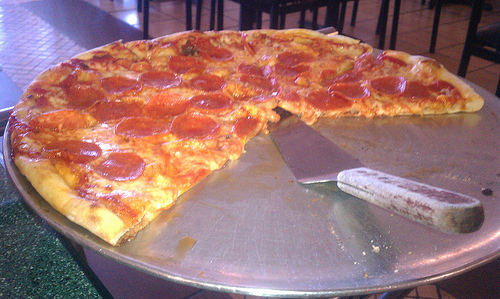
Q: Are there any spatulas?
A: Yes, there is a spatula.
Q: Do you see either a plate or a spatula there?
A: Yes, there is a spatula.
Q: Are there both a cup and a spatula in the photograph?
A: No, there is a spatula but no cups.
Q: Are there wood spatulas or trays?
A: Yes, there is a wood spatula.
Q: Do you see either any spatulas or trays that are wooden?
A: Yes, the spatula is wooden.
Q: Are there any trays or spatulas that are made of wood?
A: Yes, the spatula is made of wood.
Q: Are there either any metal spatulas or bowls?
A: Yes, there is a metal spatula.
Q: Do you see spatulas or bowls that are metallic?
A: Yes, the spatula is metallic.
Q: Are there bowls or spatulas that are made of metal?
A: Yes, the spatula is made of metal.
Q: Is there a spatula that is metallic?
A: Yes, there is a metal spatula.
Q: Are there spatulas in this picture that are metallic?
A: Yes, there is a spatula that is metallic.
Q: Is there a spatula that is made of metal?
A: Yes, there is a spatula that is made of metal.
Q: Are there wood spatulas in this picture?
A: Yes, there is a wood spatula.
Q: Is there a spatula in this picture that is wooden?
A: Yes, there is a spatula that is wooden.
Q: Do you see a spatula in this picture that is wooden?
A: Yes, there is a spatula that is wooden.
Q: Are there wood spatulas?
A: Yes, there is a spatula that is made of wood.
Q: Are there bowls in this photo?
A: No, there are no bowls.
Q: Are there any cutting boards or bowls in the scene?
A: No, there are no bowls or cutting boards.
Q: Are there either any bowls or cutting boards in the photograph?
A: No, there are no bowls or cutting boards.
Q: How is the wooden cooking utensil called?
A: The cooking utensil is a spatula.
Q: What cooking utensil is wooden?
A: The cooking utensil is a spatula.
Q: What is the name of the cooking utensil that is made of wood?
A: The cooking utensil is a spatula.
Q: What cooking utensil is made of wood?
A: The cooking utensil is a spatula.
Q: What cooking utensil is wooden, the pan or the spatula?
A: The spatula is wooden.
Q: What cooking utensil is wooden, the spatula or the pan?
A: The spatula is wooden.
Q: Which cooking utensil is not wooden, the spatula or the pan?
A: The pan is not wooden.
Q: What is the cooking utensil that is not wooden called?
A: The cooking utensil is a pan.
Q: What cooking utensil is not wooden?
A: The cooking utensil is a pan.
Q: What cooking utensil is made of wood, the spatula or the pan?
A: The spatula is made of wood.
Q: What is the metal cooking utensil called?
A: The cooking utensil is a spatula.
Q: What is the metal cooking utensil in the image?
A: The cooking utensil is a spatula.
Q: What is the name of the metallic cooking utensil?
A: The cooking utensil is a spatula.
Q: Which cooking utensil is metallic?
A: The cooking utensil is a spatula.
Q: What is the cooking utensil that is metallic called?
A: The cooking utensil is a spatula.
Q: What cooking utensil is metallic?
A: The cooking utensil is a spatula.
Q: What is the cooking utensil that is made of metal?
A: The cooking utensil is a spatula.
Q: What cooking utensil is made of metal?
A: The cooking utensil is a spatula.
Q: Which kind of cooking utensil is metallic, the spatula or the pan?
A: The spatula is metallic.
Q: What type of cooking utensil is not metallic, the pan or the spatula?
A: The pan is not metallic.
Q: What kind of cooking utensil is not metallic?
A: The cooking utensil is a pan.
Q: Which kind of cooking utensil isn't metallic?
A: The cooking utensil is a pan.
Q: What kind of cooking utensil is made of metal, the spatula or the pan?
A: The spatula is made of metal.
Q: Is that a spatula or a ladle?
A: That is a spatula.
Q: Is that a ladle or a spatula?
A: That is a spatula.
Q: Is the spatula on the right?
A: Yes, the spatula is on the right of the image.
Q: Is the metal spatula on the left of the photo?
A: No, the spatula is on the right of the image.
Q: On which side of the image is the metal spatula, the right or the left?
A: The spatula is on the right of the image.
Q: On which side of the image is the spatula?
A: The spatula is on the right of the image.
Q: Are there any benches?
A: No, there are no benches.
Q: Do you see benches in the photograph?
A: No, there are no benches.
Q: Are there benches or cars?
A: No, there are no benches or cars.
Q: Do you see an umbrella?
A: No, there are no umbrellas.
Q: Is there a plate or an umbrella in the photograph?
A: No, there are no umbrellas or plates.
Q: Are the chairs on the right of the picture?
A: Yes, the chairs are on the right of the image.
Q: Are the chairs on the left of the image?
A: No, the chairs are on the right of the image.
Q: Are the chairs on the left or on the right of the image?
A: The chairs are on the right of the image.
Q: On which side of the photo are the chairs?
A: The chairs are on the right of the image.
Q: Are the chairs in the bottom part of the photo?
A: No, the chairs are in the top of the image.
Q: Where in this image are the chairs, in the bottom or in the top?
A: The chairs are in the top of the image.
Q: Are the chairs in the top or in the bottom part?
A: The chairs are in the top of the image.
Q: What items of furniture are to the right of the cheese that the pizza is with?
A: The pieces of furniture are chairs.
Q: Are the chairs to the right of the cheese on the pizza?
A: Yes, the chairs are to the right of the cheese.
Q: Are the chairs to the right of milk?
A: No, the chairs are to the right of the cheese.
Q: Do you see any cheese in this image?
A: Yes, there is cheese.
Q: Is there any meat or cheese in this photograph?
A: Yes, there is cheese.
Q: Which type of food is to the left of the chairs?
A: The food is cheese.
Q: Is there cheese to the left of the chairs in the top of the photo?
A: Yes, there is cheese to the left of the chairs.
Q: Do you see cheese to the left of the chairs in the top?
A: Yes, there is cheese to the left of the chairs.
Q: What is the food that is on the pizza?
A: The food is cheese.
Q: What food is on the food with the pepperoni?
A: The food is cheese.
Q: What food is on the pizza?
A: The food is cheese.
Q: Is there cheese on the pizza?
A: Yes, there is cheese on the pizza.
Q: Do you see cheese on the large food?
A: Yes, there is cheese on the pizza.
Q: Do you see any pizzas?
A: Yes, there is a pizza.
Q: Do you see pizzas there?
A: Yes, there is a pizza.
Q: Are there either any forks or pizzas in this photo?
A: Yes, there is a pizza.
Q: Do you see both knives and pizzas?
A: No, there is a pizza but no knives.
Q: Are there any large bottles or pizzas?
A: Yes, there is a large pizza.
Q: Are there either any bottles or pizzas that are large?
A: Yes, the pizza is large.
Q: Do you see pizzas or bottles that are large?
A: Yes, the pizza is large.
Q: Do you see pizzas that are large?
A: Yes, there is a large pizza.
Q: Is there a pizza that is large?
A: Yes, there is a pizza that is large.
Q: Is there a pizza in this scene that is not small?
A: Yes, there is a large pizza.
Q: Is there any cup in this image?
A: No, there are no cups.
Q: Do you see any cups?
A: No, there are no cups.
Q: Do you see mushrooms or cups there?
A: No, there are no cups or mushrooms.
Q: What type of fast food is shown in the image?
A: The fast food is a pizza.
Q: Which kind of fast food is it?
A: The food is a pizza.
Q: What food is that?
A: This is a pizza.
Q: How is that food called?
A: This is a pizza.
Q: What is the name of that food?
A: This is a pizza.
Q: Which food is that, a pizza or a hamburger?
A: This is a pizza.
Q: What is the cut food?
A: The food is a pizza.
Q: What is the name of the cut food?
A: The food is a pizza.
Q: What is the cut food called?
A: The food is a pizza.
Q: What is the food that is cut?
A: The food is a pizza.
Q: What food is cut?
A: The food is a pizza.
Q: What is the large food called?
A: The food is a pizza.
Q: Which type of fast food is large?
A: The fast food is a pizza.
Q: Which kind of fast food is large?
A: The fast food is a pizza.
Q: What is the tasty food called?
A: The food is a pizza.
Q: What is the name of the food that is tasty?
A: The food is a pizza.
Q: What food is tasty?
A: The food is a pizza.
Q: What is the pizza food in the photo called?
A: The food is a pizza.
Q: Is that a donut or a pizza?
A: That is a pizza.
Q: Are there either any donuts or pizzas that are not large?
A: No, there is a pizza but it is large.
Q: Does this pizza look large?
A: Yes, the pizza is large.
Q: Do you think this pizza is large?
A: Yes, the pizza is large.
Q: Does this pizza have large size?
A: Yes, the pizza is large.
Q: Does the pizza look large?
A: Yes, the pizza is large.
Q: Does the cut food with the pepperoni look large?
A: Yes, the pizza is large.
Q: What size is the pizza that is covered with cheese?
A: The pizza is large.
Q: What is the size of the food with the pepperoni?
A: The pizza is large.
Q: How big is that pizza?
A: The pizza is large.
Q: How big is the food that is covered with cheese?
A: The pizza is large.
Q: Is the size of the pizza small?
A: No, the pizza is large.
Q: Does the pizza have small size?
A: No, the pizza is large.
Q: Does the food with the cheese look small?
A: No, the pizza is large.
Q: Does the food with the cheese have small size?
A: No, the pizza is large.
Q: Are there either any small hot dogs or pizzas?
A: No, there is a pizza but it is large.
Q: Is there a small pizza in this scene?
A: No, there is a pizza but it is large.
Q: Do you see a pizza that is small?
A: No, there is a pizza but it is large.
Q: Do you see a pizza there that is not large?
A: No, there is a pizza but it is large.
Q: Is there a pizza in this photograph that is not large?
A: No, there is a pizza but it is large.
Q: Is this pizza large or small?
A: The pizza is large.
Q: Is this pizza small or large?
A: The pizza is large.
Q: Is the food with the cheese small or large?
A: The pizza is large.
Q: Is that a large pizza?
A: Yes, that is a large pizza.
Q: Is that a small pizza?
A: No, that is a large pizza.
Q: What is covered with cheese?
A: The pizza is covered with cheese.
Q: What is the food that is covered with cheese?
A: The food is a pizza.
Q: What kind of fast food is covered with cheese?
A: The food is a pizza.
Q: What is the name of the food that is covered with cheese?
A: The food is a pizza.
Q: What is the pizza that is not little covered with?
A: The pizza is covered with cheese.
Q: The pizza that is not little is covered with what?
A: The pizza is covered with cheese.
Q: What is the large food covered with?
A: The pizza is covered with cheese.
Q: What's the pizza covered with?
A: The pizza is covered with cheese.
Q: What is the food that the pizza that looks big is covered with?
A: The food is cheese.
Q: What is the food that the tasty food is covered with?
A: The food is cheese.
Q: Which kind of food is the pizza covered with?
A: The pizza is covered with cheese.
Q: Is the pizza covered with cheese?
A: Yes, the pizza is covered with cheese.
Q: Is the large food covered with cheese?
A: Yes, the pizza is covered with cheese.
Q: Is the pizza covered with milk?
A: No, the pizza is covered with cheese.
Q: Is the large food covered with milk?
A: No, the pizza is covered with cheese.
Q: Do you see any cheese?
A: Yes, there is cheese.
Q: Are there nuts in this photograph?
A: No, there are no nuts.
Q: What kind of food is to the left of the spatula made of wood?
A: The food is cheese.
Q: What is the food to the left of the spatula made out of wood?
A: The food is cheese.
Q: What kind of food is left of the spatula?
A: The food is cheese.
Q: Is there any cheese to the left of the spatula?
A: Yes, there is cheese to the left of the spatula.